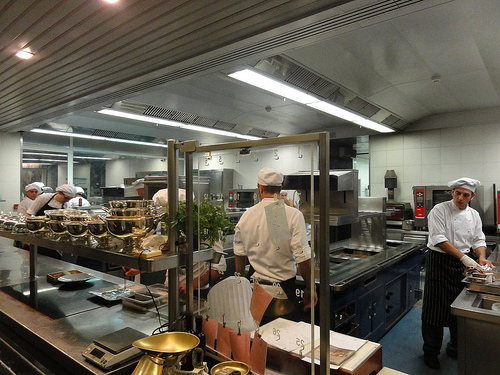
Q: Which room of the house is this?
A: It is a kitchen.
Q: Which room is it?
A: It is a kitchen.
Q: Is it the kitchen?
A: Yes, it is the kitchen.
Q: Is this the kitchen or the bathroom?
A: It is the kitchen.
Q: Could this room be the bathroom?
A: No, it is the kitchen.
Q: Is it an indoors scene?
A: Yes, it is indoors.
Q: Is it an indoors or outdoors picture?
A: It is indoors.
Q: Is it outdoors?
A: No, it is indoors.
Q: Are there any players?
A: No, there are no players.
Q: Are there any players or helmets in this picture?
A: No, there are no players or helmets.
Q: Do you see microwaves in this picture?
A: Yes, there is a microwave.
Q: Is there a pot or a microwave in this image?
A: Yes, there is a microwave.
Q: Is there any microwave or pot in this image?
A: Yes, there is a microwave.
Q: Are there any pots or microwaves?
A: Yes, there is a microwave.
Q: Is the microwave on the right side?
A: Yes, the microwave is on the right of the image.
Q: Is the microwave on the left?
A: No, the microwave is on the right of the image.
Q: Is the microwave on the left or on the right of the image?
A: The microwave is on the right of the image.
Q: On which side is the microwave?
A: The microwave is on the right of the image.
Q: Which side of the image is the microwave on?
A: The microwave is on the right of the image.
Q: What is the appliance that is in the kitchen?
A: The appliance is a microwave.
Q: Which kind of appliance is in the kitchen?
A: The appliance is a microwave.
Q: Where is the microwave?
A: The microwave is in the kitchen.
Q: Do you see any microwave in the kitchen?
A: Yes, there is a microwave in the kitchen.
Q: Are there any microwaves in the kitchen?
A: Yes, there is a microwave in the kitchen.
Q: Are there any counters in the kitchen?
A: No, there is a microwave in the kitchen.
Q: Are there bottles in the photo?
A: No, there are no bottles.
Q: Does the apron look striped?
A: Yes, the apron is striped.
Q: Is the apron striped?
A: Yes, the apron is striped.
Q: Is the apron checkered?
A: No, the apron is striped.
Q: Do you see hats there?
A: Yes, there is a hat.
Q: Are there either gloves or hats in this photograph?
A: Yes, there is a hat.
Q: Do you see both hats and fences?
A: No, there is a hat but no fences.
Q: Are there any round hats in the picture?
A: Yes, there is a round hat.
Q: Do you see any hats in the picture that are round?
A: Yes, there is a hat that is round.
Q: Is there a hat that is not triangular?
A: Yes, there is a round hat.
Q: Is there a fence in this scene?
A: No, there are no fences.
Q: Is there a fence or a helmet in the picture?
A: No, there are no fences or helmets.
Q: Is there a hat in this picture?
A: Yes, there is a hat.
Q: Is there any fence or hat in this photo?
A: Yes, there is a hat.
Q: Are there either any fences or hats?
A: Yes, there is a hat.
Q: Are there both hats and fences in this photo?
A: No, there is a hat but no fences.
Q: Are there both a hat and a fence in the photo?
A: No, there is a hat but no fences.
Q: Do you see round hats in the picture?
A: Yes, there is a round hat.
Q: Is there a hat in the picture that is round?
A: Yes, there is a hat that is round.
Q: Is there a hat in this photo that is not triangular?
A: Yes, there is a round hat.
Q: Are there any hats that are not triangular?
A: Yes, there is a round hat.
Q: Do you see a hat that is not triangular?
A: Yes, there is a round hat.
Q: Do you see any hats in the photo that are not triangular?
A: Yes, there is a round hat.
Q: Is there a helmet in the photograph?
A: No, there are no helmets.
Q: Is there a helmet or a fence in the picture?
A: No, there are no helmets or fences.